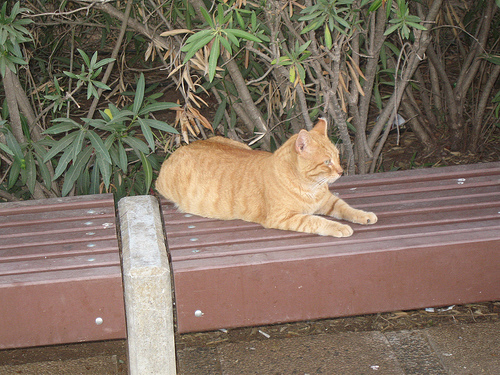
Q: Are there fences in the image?
A: No, there are no fences.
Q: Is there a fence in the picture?
A: No, there are no fences.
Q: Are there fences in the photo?
A: No, there are no fences.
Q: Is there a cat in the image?
A: Yes, there is a cat.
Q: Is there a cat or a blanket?
A: Yes, there is a cat.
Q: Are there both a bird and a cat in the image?
A: No, there is a cat but no birds.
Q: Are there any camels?
A: No, there are no camels.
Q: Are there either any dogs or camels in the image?
A: No, there are no camels or dogs.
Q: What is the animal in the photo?
A: The animal is a cat.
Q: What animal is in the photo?
A: The animal is a cat.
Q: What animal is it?
A: The animal is a cat.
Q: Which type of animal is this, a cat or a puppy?
A: That is a cat.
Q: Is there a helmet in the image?
A: No, there are no helmets.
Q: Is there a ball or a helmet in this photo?
A: No, there are no helmets or balls.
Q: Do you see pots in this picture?
A: No, there are no pots.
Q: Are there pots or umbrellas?
A: No, there are no pots or umbrellas.